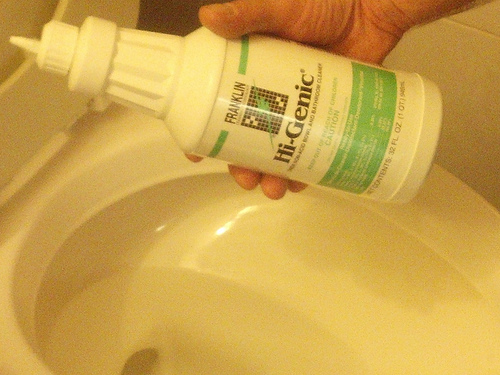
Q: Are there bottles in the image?
A: Yes, there is a bottle.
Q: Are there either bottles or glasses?
A: Yes, there is a bottle.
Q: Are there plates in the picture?
A: No, there are no plates.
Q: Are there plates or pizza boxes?
A: No, there are no plates or pizza boxes.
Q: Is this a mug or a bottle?
A: This is a bottle.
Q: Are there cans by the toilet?
A: No, there is a bottle by the toilet.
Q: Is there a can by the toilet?
A: No, there is a bottle by the toilet.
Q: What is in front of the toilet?
A: The bottle is in front of the toilet.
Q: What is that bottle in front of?
A: The bottle is in front of the toilet.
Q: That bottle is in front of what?
A: The bottle is in front of the toilet.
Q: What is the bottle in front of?
A: The bottle is in front of the toilet.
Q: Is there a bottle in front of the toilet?
A: Yes, there is a bottle in front of the toilet.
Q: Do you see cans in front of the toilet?
A: No, there is a bottle in front of the toilet.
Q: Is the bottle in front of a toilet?
A: Yes, the bottle is in front of a toilet.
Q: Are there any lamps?
A: No, there are no lamps.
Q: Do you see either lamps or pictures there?
A: No, there are no lamps or pictures.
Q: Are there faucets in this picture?
A: No, there are no faucets.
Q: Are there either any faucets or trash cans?
A: No, there are no faucets or trash cans.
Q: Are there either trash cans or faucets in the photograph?
A: No, there are no faucets or trash cans.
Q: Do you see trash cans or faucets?
A: No, there are no faucets or trash cans.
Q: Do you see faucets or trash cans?
A: No, there are no faucets or trash cans.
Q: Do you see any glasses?
A: No, there are no glasses.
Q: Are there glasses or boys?
A: No, there are no glasses or boys.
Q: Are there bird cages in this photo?
A: No, there are no bird cages.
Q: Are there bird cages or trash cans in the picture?
A: No, there are no bird cages or trash cans.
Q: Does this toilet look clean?
A: Yes, the toilet is clean.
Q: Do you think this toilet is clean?
A: Yes, the toilet is clean.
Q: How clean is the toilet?
A: The toilet is clean.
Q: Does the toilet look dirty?
A: No, the toilet is clean.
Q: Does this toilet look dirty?
A: No, the toilet is clean.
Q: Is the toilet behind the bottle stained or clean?
A: The toilet is clean.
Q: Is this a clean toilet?
A: Yes, this is a clean toilet.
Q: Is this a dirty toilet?
A: No, this is a clean toilet.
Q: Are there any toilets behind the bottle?
A: Yes, there is a toilet behind the bottle.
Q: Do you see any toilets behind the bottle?
A: Yes, there is a toilet behind the bottle.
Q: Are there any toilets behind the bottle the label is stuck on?
A: Yes, there is a toilet behind the bottle.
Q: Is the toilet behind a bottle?
A: Yes, the toilet is behind a bottle.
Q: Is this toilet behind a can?
A: No, the toilet is behind a bottle.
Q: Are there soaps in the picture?
A: No, there are no soaps.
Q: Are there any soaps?
A: No, there are no soaps.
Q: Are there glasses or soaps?
A: No, there are no soaps or glasses.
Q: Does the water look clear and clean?
A: Yes, the water is clear and clean.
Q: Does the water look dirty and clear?
A: No, the water is clear but clean.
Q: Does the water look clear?
A: Yes, the water is clear.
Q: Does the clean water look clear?
A: Yes, the water is clear.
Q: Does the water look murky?
A: No, the water is clear.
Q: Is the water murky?
A: No, the water is clear.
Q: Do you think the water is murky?
A: No, the water is clear.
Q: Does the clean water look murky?
A: No, the water is clear.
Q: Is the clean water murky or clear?
A: The water is clear.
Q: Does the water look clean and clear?
A: Yes, the water is clean and clear.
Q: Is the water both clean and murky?
A: No, the water is clean but clear.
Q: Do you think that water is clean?
A: Yes, the water is clean.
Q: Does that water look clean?
A: Yes, the water is clean.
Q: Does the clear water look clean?
A: Yes, the water is clean.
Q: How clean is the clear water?
A: The water is clean.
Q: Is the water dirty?
A: No, the water is clean.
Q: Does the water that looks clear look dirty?
A: No, the water is clean.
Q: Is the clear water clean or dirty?
A: The water is clean.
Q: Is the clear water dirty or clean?
A: The water is clean.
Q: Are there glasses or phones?
A: No, there are no glasses or phones.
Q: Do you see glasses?
A: No, there are no glasses.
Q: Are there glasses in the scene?
A: No, there are no glasses.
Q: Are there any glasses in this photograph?
A: No, there are no glasses.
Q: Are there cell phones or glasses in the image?
A: No, there are no glasses or cell phones.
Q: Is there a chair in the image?
A: No, there are no chairs.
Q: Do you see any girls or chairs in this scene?
A: No, there are no chairs or girls.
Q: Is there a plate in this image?
A: No, there are no plates.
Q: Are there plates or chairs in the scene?
A: No, there are no plates or chairs.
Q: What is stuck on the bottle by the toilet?
A: The label is stuck on the bottle.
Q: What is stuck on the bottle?
A: The label is stuck on the bottle.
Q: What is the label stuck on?
A: The label is stuck on the bottle.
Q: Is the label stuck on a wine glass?
A: No, the label is stuck on the bottle.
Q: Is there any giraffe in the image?
A: No, there are no giraffes.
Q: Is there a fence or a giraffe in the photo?
A: No, there are no giraffes or fences.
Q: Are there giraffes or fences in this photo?
A: No, there are no giraffes or fences.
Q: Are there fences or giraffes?
A: No, there are no giraffes or fences.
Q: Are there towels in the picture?
A: No, there are no towels.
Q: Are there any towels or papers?
A: No, there are no towels or papers.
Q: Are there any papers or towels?
A: No, there are no towels or papers.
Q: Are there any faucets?
A: No, there are no faucets.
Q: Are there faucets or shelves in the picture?
A: No, there are no faucets or shelves.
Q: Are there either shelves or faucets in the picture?
A: No, there are no faucets or shelves.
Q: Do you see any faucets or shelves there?
A: No, there are no faucets or shelves.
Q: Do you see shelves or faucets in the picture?
A: No, there are no faucets or shelves.